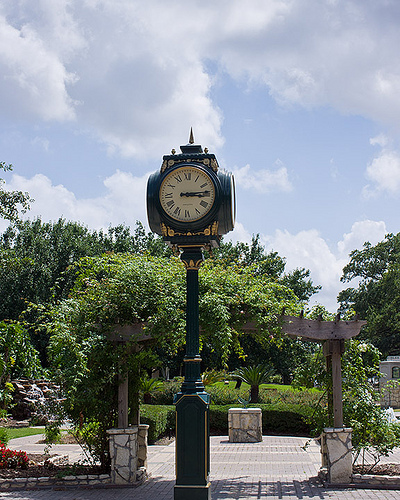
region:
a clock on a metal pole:
[156, 166, 217, 223]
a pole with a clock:
[140, 125, 237, 498]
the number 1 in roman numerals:
[192, 171, 202, 184]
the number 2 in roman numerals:
[200, 181, 208, 187]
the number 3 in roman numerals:
[199, 189, 210, 198]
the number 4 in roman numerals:
[196, 199, 208, 209]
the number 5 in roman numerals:
[192, 207, 201, 215]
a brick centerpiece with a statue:
[228, 393, 265, 443]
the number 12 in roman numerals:
[182, 171, 191, 181]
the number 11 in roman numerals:
[173, 174, 182, 185]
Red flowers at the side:
[0, 437, 33, 473]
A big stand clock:
[132, 122, 261, 273]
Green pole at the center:
[163, 257, 237, 497]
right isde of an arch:
[270, 304, 369, 488]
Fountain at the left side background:
[8, 376, 78, 432]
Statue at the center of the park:
[221, 389, 270, 443]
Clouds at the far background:
[297, 214, 398, 256]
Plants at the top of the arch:
[48, 253, 180, 438]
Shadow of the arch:
[219, 473, 321, 497]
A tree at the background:
[339, 230, 397, 295]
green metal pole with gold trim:
[142, 121, 247, 494]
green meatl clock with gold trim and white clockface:
[136, 121, 250, 275]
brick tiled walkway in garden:
[11, 413, 396, 498]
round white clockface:
[160, 162, 217, 223]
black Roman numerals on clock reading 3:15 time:
[165, 168, 214, 217]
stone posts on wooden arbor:
[103, 415, 356, 492]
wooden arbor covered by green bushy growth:
[104, 301, 372, 426]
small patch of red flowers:
[0, 447, 30, 469]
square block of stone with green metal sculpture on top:
[228, 393, 266, 442]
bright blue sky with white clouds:
[0, 0, 398, 309]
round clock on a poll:
[153, 157, 218, 223]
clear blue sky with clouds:
[78, 72, 180, 136]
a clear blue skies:
[254, 117, 299, 154]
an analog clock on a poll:
[150, 163, 230, 230]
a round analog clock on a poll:
[155, 159, 223, 225]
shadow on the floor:
[235, 472, 317, 498]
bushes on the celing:
[80, 265, 283, 314]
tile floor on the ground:
[244, 454, 298, 485]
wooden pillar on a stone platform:
[309, 340, 352, 424]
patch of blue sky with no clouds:
[267, 111, 315, 158]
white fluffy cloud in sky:
[79, 16, 196, 116]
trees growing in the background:
[370, 241, 397, 346]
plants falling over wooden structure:
[70, 262, 168, 317]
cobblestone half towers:
[108, 429, 141, 484]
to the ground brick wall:
[0, 477, 110, 485]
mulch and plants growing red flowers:
[1, 447, 98, 473]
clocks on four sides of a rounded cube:
[145, 141, 239, 241]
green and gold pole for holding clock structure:
[174, 250, 214, 499]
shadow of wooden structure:
[226, 479, 320, 497]